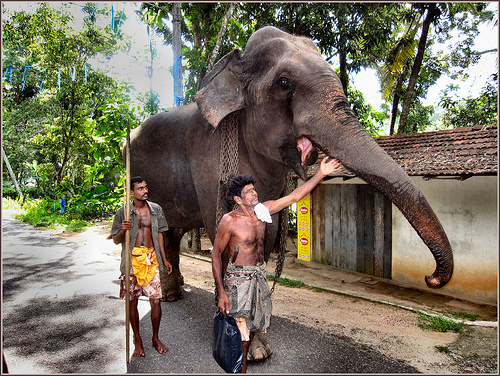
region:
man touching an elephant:
[185, 66, 476, 374]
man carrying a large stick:
[96, 102, 182, 374]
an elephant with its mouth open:
[183, 6, 497, 300]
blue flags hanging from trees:
[0, 3, 169, 93]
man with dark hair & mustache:
[98, 172, 183, 240]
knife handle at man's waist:
[204, 228, 289, 325]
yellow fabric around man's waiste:
[116, 237, 183, 309]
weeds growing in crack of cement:
[313, 294, 490, 354]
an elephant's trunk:
[355, 127, 470, 301]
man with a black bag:
[199, 159, 294, 374]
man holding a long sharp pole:
[120, 117, 138, 371]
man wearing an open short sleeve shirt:
[113, 200, 168, 272]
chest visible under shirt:
[131, 205, 158, 245]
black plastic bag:
[211, 311, 244, 371]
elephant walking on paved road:
[0, 214, 425, 374]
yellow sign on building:
[298, 193, 315, 259]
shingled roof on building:
[308, 128, 498, 175]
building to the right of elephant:
[298, 132, 498, 309]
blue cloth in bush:
[59, 195, 67, 212]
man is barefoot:
[110, 175, 178, 356]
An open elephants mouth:
[279, 130, 317, 171]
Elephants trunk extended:
[312, 113, 463, 299]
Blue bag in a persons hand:
[205, 303, 245, 374]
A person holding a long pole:
[101, 108, 177, 365]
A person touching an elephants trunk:
[207, 144, 357, 374]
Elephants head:
[181, 8, 469, 300]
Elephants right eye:
[255, 63, 301, 109]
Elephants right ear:
[190, 38, 249, 131]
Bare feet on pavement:
[132, 332, 172, 359]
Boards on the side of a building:
[309, 186, 397, 283]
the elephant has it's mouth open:
[274, 127, 333, 202]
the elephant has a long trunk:
[330, 122, 427, 226]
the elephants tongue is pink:
[288, 128, 317, 178]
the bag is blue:
[212, 317, 234, 346]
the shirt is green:
[151, 206, 163, 233]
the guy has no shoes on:
[128, 335, 175, 353]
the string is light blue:
[20, 60, 108, 97]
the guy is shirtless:
[221, 209, 273, 258]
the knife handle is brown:
[228, 241, 244, 271]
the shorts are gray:
[230, 278, 252, 303]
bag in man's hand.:
[212, 320, 244, 368]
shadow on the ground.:
[29, 300, 65, 343]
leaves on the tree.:
[93, 141, 108, 196]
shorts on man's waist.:
[233, 273, 260, 303]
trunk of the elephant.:
[357, 157, 423, 223]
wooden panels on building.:
[312, 209, 369, 247]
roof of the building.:
[427, 140, 477, 159]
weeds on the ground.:
[427, 313, 454, 330]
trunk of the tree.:
[168, 35, 183, 97]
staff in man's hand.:
[122, 251, 138, 345]